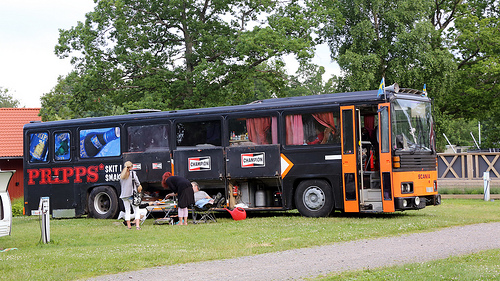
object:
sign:
[27, 163, 105, 185]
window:
[227, 114, 279, 146]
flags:
[377, 74, 387, 102]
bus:
[21, 73, 441, 219]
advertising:
[240, 152, 266, 169]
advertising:
[187, 156, 212, 172]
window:
[392, 98, 436, 154]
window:
[176, 120, 222, 148]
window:
[126, 124, 169, 152]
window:
[28, 132, 50, 163]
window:
[79, 126, 120, 159]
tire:
[88, 186, 120, 219]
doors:
[339, 102, 393, 212]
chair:
[191, 192, 225, 225]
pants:
[177, 207, 188, 218]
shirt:
[166, 176, 192, 194]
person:
[118, 160, 143, 230]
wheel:
[294, 178, 335, 217]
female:
[161, 171, 196, 225]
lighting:
[402, 200, 407, 207]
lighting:
[415, 196, 421, 205]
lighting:
[402, 183, 405, 192]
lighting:
[406, 183, 412, 192]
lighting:
[434, 180, 437, 192]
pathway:
[74, 217, 499, 279]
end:
[382, 92, 451, 212]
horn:
[383, 83, 400, 94]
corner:
[377, 76, 400, 102]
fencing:
[436, 153, 465, 179]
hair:
[161, 171, 172, 190]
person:
[191, 181, 222, 212]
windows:
[285, 108, 341, 148]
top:
[389, 88, 431, 109]